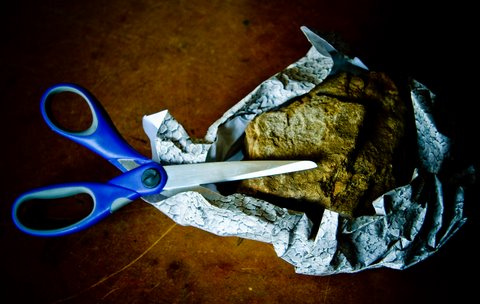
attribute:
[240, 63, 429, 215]
brown rock — large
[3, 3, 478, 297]
floor — dark brown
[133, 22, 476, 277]
paper — crumbled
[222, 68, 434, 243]
stone — big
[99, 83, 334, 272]
area — metallic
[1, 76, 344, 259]
scissors — silver, Blue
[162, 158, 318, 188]
blades — sharp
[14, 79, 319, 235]
scissors — Blue, silver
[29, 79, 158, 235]
handle — Blue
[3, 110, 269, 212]
scissors — silver, Blue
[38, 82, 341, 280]
scissors — blue, silver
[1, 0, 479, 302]
table — brown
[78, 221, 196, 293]
scratch — white